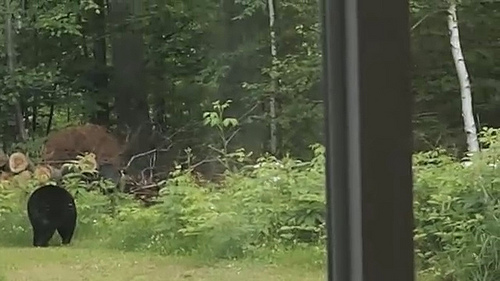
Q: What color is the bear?
A: Black.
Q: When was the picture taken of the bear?
A: The Daytime.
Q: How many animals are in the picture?
A: One.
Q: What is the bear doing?
A: Walking.